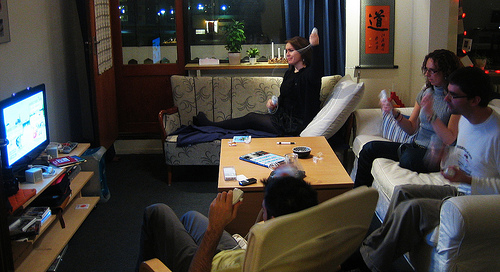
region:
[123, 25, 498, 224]
four people playing Wii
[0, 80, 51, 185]
an LCD TV screen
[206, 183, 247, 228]
a hand holding a Wii remote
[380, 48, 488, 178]
two people playing Wii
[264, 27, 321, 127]
a woman playing Wii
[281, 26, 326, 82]
a woman holding up a Wii remote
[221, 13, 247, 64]
a small potted plant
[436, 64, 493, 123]
a man wearing glasses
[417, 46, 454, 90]
a woman wearing glasses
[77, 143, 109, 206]
an Apple computer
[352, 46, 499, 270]
Two people sitting on a white couch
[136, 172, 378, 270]
The guy is sitting in a white chair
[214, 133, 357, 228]
A wood coffee table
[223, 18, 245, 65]
A tall indoor plant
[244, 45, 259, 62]
A small indoor plant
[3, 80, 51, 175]
A small flat screen television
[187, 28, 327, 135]
The girl is playing a video game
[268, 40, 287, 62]
Three white candles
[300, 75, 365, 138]
A white pillow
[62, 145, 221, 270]
The carpet is blue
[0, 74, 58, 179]
a flat screen tv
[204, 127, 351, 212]
wood coffee table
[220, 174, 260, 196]
a cell phone on a table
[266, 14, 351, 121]
a woman holding a game controller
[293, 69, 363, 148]
a white pillow on a couch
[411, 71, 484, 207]
a man holding a game controller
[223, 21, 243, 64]
a plant in a pot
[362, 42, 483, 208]
two people sitting on a couch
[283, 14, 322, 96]
a woman with her arm raised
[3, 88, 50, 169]
tv facing crowd of people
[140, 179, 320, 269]
person sitting with remote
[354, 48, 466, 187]
person sitting with remote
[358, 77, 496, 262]
person sitting with remote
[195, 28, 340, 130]
person sitting with remote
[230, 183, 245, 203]
remote in person's hand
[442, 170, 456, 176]
remote in person's hand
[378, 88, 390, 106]
remote in person's hand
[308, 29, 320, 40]
remote in person's hand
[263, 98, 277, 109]
remote in person's hand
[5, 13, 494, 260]
people playing video game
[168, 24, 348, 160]
girl in black sweater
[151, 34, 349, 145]
girl on white sofa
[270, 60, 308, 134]
black sweater on girl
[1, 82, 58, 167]
tv on tv console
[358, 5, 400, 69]
japanese art on wall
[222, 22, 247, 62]
green plant on counter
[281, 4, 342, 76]
black curtain on window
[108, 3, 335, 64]
window with black curtain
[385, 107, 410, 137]
stripped pillow on couch